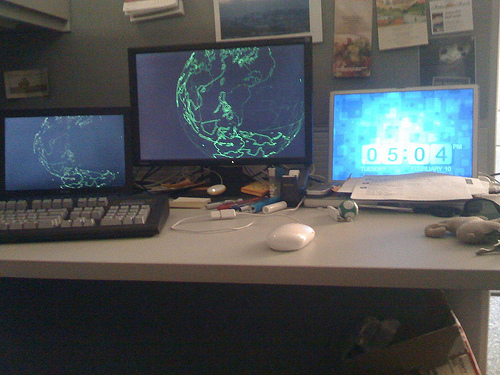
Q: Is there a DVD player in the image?
A: No, there are no DVD players.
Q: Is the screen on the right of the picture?
A: Yes, the screen is on the right of the image.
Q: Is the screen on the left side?
A: No, the screen is on the right of the image.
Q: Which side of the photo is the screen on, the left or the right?
A: The screen is on the right of the image.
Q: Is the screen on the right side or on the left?
A: The screen is on the right of the image.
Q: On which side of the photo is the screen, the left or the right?
A: The screen is on the right of the image.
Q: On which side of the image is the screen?
A: The screen is on the right of the image.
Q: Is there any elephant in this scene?
A: Yes, there is an elephant.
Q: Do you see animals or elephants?
A: Yes, there is an elephant.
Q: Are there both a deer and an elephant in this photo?
A: No, there is an elephant but no deer.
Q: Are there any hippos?
A: No, there are no hippos.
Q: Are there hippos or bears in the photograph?
A: No, there are no hippos or bears.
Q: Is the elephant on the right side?
A: Yes, the elephant is on the right of the image.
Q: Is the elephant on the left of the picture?
A: No, the elephant is on the right of the image.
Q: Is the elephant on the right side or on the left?
A: The elephant is on the right of the image.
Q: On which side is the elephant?
A: The elephant is on the right of the image.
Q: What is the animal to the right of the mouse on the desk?
A: The animal is an elephant.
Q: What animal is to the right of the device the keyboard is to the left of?
A: The animal is an elephant.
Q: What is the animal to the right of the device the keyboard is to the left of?
A: The animal is an elephant.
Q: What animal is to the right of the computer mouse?
A: The animal is an elephant.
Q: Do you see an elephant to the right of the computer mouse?
A: Yes, there is an elephant to the right of the computer mouse.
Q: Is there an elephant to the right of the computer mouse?
A: Yes, there is an elephant to the right of the computer mouse.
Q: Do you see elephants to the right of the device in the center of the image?
A: Yes, there is an elephant to the right of the computer mouse.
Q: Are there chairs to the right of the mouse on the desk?
A: No, there is an elephant to the right of the computer mouse.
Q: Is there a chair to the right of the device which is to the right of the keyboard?
A: No, there is an elephant to the right of the computer mouse.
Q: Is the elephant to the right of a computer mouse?
A: Yes, the elephant is to the right of a computer mouse.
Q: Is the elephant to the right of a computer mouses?
A: No, the elephant is to the right of a computer mouse.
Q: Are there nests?
A: No, there are no nests.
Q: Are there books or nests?
A: No, there are no nests or books.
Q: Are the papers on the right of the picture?
A: Yes, the papers are on the right of the image.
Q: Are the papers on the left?
A: No, the papers are on the right of the image.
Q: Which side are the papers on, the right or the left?
A: The papers are on the right of the image.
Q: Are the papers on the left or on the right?
A: The papers are on the right of the image.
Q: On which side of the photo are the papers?
A: The papers are on the right of the image.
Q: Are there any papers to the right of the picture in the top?
A: Yes, there are papers to the right of the picture.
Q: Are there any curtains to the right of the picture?
A: No, there are papers to the right of the picture.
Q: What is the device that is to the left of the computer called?
A: The device is a monitor.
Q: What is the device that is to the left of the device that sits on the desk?
A: The device is a monitor.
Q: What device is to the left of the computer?
A: The device is a monitor.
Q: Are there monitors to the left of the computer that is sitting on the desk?
A: Yes, there is a monitor to the left of the computer.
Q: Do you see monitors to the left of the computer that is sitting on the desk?
A: Yes, there is a monitor to the left of the computer.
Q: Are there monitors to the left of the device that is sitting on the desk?
A: Yes, there is a monitor to the left of the computer.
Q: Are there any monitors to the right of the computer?
A: No, the monitor is to the left of the computer.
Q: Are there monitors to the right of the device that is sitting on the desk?
A: No, the monitor is to the left of the computer.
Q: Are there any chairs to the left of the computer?
A: No, there is a monitor to the left of the computer.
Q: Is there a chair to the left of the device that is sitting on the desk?
A: No, there is a monitor to the left of the computer.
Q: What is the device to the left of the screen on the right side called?
A: The device is a monitor.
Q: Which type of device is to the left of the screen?
A: The device is a monitor.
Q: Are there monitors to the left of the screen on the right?
A: Yes, there is a monitor to the left of the screen.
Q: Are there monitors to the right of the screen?
A: No, the monitor is to the left of the screen.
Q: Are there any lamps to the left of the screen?
A: No, there is a monitor to the left of the screen.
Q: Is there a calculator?
A: No, there are no calculators.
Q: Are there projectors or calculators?
A: No, there are no calculators or projectors.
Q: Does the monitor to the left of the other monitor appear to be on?
A: Yes, the monitor is on.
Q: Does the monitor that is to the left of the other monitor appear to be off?
A: No, the monitor is on.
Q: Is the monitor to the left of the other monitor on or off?
A: The monitor is on.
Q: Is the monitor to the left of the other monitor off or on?
A: The monitor is on.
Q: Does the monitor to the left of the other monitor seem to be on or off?
A: The monitor is on.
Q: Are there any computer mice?
A: Yes, there is a computer mouse.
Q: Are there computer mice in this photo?
A: Yes, there is a computer mouse.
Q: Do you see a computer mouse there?
A: Yes, there is a computer mouse.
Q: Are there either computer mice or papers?
A: Yes, there is a computer mouse.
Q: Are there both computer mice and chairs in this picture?
A: No, there is a computer mouse but no chairs.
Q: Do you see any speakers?
A: No, there are no speakers.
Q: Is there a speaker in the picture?
A: No, there are no speakers.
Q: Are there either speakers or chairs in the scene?
A: No, there are no speakers or chairs.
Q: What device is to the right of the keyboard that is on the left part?
A: The device is a computer mouse.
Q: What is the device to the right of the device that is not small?
A: The device is a computer mouse.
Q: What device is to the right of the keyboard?
A: The device is a computer mouse.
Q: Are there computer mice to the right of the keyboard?
A: Yes, there is a computer mouse to the right of the keyboard.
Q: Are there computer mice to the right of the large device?
A: Yes, there is a computer mouse to the right of the keyboard.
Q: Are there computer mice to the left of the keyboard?
A: No, the computer mouse is to the right of the keyboard.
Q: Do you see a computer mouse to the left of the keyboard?
A: No, the computer mouse is to the right of the keyboard.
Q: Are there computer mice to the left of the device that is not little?
A: No, the computer mouse is to the right of the keyboard.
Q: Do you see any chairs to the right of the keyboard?
A: No, there is a computer mouse to the right of the keyboard.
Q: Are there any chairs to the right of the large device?
A: No, there is a computer mouse to the right of the keyboard.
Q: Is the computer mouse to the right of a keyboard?
A: Yes, the computer mouse is to the right of a keyboard.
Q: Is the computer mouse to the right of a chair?
A: No, the computer mouse is to the right of a keyboard.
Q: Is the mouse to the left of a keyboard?
A: No, the mouse is to the right of a keyboard.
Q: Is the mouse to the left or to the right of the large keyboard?
A: The mouse is to the right of the keyboard.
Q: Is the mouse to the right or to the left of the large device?
A: The mouse is to the right of the keyboard.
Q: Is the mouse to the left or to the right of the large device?
A: The mouse is to the right of the keyboard.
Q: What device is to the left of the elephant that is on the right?
A: The device is a computer mouse.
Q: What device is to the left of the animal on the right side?
A: The device is a computer mouse.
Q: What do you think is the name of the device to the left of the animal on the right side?
A: The device is a computer mouse.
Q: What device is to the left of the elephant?
A: The device is a computer mouse.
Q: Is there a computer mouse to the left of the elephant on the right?
A: Yes, there is a computer mouse to the left of the elephant.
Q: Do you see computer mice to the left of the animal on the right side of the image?
A: Yes, there is a computer mouse to the left of the elephant.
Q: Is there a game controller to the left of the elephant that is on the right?
A: No, there is a computer mouse to the left of the elephant.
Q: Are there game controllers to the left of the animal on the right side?
A: No, there is a computer mouse to the left of the elephant.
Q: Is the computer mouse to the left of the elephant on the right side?
A: Yes, the computer mouse is to the left of the elephant.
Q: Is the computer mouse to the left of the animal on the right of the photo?
A: Yes, the computer mouse is to the left of the elephant.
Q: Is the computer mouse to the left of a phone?
A: No, the computer mouse is to the left of the elephant.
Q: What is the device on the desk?
A: The device is a computer mouse.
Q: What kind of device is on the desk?
A: The device is a computer mouse.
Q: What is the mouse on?
A: The mouse is on the desk.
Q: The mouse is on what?
A: The mouse is on the desk.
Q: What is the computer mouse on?
A: The mouse is on the desk.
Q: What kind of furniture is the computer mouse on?
A: The computer mouse is on the desk.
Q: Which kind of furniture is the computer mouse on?
A: The computer mouse is on the desk.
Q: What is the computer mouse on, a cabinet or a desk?
A: The computer mouse is on a desk.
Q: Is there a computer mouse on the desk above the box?
A: Yes, there is a computer mouse on the desk.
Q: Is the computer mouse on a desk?
A: Yes, the computer mouse is on a desk.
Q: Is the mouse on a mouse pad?
A: No, the mouse is on a desk.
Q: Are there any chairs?
A: No, there are no chairs.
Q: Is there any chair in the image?
A: No, there are no chairs.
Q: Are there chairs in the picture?
A: No, there are no chairs.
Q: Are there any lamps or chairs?
A: No, there are no chairs or lamps.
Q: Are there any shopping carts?
A: No, there are no shopping carts.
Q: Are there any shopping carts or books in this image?
A: No, there are no shopping carts or books.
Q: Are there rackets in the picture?
A: No, there are no rackets.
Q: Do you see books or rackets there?
A: No, there are no rackets or books.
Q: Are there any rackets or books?
A: No, there are no rackets or books.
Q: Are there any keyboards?
A: Yes, there is a keyboard.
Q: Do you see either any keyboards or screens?
A: Yes, there is a keyboard.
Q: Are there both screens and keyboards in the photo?
A: Yes, there are both a keyboard and a screen.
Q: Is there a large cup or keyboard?
A: Yes, there is a large keyboard.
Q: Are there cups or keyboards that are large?
A: Yes, the keyboard is large.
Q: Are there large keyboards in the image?
A: Yes, there is a large keyboard.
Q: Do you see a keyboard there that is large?
A: Yes, there is a keyboard that is large.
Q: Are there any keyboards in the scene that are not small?
A: Yes, there is a large keyboard.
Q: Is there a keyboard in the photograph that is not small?
A: Yes, there is a large keyboard.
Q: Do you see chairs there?
A: No, there are no chairs.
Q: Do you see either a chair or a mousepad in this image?
A: No, there are no chairs or mouse pads.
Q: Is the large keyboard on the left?
A: Yes, the keyboard is on the left of the image.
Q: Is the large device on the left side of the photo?
A: Yes, the keyboard is on the left of the image.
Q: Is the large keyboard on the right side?
A: No, the keyboard is on the left of the image.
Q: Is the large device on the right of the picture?
A: No, the keyboard is on the left of the image.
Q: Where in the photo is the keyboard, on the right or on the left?
A: The keyboard is on the left of the image.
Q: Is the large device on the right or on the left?
A: The keyboard is on the left of the image.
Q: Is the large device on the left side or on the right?
A: The keyboard is on the left of the image.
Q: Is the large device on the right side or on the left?
A: The keyboard is on the left of the image.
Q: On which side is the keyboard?
A: The keyboard is on the left of the image.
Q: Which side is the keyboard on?
A: The keyboard is on the left of the image.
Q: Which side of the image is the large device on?
A: The keyboard is on the left of the image.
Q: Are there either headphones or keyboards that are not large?
A: No, there is a keyboard but it is large.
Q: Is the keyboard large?
A: Yes, the keyboard is large.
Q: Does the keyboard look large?
A: Yes, the keyboard is large.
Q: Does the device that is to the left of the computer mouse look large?
A: Yes, the keyboard is large.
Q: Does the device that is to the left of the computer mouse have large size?
A: Yes, the keyboard is large.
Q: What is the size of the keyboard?
A: The keyboard is large.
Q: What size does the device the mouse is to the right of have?
A: The keyboard has large size.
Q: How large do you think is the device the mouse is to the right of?
A: The keyboard is large.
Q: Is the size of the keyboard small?
A: No, the keyboard is large.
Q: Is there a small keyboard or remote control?
A: No, there is a keyboard but it is large.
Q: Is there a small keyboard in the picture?
A: No, there is a keyboard but it is large.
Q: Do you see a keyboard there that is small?
A: No, there is a keyboard but it is large.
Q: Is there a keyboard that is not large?
A: No, there is a keyboard but it is large.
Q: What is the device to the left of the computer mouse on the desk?
A: The device is a keyboard.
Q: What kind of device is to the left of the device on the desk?
A: The device is a keyboard.